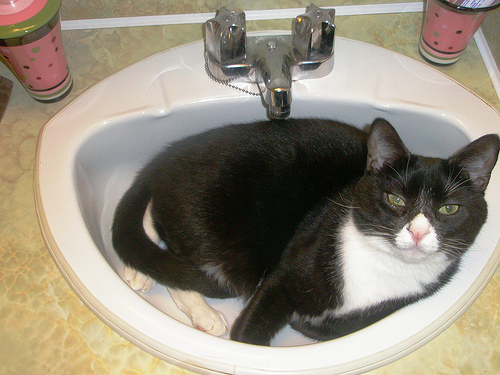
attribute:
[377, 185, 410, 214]
eye — green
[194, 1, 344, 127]
faucet — stainless , steel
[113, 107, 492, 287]
cat — black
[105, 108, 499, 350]
cat — black and white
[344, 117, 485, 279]
cat — black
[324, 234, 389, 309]
fur — white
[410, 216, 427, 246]
nose — pink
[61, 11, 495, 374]
sink — white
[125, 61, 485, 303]
sink — white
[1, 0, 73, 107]
cup — pink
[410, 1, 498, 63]
cup — decorated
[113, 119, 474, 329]
cat — black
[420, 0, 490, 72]
glass — pink, lined, dotted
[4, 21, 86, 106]
glass — pink, lined, dotted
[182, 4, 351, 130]
tap — silver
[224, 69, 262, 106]
chain — metal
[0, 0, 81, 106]
cup — colorful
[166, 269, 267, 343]
paws — white